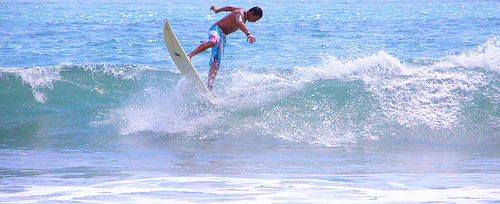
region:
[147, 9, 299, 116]
a man on a surf board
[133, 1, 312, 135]
a man surfing the waves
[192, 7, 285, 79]
a man wearing shorts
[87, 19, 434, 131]
a medium size wave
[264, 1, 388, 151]
the beautiful blue ocean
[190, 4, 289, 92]
a man looking down at the wave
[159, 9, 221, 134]
a white surf board in the water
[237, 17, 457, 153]
splashing waves in the water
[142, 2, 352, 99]
a man surfing in the ocean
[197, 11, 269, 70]
a man wearing blue and white shorts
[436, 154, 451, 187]
Small ripples in the water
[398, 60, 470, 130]
Small ripples in the water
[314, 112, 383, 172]
Small ripples in the water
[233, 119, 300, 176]
Small ripples in the water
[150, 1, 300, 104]
Person in the water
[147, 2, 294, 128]
PErson on a surfboard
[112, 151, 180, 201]
Small ripples in the water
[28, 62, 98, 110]
Small ripples in the water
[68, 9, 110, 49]
Small ripples in the water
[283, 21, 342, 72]
Small ripples in the water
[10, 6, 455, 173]
a surfer in the sea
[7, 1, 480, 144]
surfer over a wave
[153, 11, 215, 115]
a surfboard color white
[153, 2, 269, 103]
surfer has blue and red shorts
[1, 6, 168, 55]
water of ocean is blue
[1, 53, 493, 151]
a wave rolling in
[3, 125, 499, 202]
water is foamy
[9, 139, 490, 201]
white foam formed on the water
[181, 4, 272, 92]
surfer has black hair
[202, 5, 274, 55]
surfer has extended arms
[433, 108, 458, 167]
Ripples in the water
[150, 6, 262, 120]
PErson in the water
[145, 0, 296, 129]
PErson on a surf board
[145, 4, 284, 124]
Man surfing in the water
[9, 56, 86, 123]
Ripples in the water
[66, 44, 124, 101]
Ripples in the water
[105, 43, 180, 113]
Ripples in the water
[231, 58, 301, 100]
Ripples in the water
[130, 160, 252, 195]
Ripples in the water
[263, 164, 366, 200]
Ripples in the water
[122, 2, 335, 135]
a man is surfboarding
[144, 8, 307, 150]
a man on a surfboard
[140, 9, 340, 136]
a man riding a surfboard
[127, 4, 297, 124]
a man surfing a wave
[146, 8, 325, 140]
a surfer on a surfboard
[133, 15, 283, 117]
a surfer on the water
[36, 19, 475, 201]
a body of water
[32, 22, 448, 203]
a body of blue water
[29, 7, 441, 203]
a body of water that is blue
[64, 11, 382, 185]
a body of water with a surfer